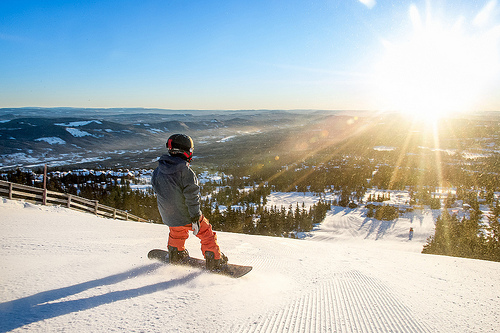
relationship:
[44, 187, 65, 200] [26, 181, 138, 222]
board on fence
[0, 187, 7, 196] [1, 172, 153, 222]
wooden board on fence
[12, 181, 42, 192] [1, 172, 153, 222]
wooden board on fence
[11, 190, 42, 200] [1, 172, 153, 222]
wooden board on fence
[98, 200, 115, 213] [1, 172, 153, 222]
wooden board on fence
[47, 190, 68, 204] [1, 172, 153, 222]
board on fence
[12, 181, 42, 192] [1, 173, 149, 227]
wooden board on fence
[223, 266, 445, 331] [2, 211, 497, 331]
straight lines on snow